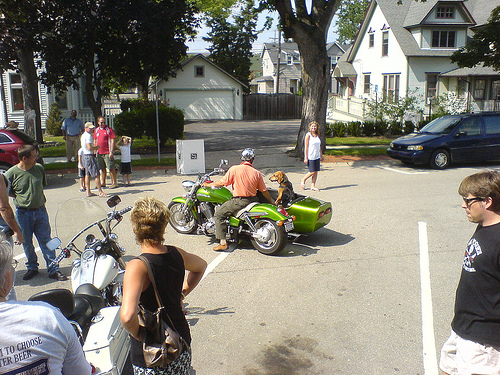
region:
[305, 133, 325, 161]
woman wearing a white tank top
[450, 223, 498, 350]
guy wearing a black tshirt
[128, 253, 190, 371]
brown purse over the woman's shoulder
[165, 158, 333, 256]
green motorcycle with side car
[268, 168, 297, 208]
dog sitting in green motorcycle side car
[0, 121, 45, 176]
red car parked on the side of the street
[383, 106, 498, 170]
van parked on the side of the street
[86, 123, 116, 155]
man wearing a red shirt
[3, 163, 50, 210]
man wearing a dark green shirt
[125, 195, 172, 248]
woman with blonde short hair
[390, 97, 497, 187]
Blue car parked in street.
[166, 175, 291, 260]
Green lime bike in lot.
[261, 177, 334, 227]
Lime green motorcycle sidecar.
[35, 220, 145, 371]
White motorcycle in lot.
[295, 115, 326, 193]
Woman in white shirt and blue shorts.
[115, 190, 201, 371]
Woman wearing black top.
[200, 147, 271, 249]
Man on lime green motorcycle.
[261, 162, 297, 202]
Dog in lime green sidecar.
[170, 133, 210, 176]
White box on street corner.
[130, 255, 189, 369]
Brown purse carried by a woman.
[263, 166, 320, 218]
dog in the sidecar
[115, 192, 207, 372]
woman with a pocketbook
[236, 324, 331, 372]
grease spot on the road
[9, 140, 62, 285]
guy with green shirt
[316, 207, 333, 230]
lights on the sidecar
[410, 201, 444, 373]
white stripe on the road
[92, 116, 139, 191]
kid next to the man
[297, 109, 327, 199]
woman with white shirt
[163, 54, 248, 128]
white garage with window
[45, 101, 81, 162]
guy standing near a bush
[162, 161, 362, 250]
Green motorcycle with sidecar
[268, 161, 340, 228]
Brown dog sitting in sidecar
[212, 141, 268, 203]
Man in silver helmet and orange shirt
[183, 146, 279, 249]
Man astride green motorcycle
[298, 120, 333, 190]
Woman in white top and blue shorts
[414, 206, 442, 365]
White parking stripe on pavement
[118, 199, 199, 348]
Blonde woman in sleeveless top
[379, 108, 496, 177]
Blue van paralleled parked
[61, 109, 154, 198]
Two adults and two children bystanders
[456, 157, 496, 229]
Blonde man with sunglasses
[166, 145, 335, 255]
man and dog in green motorcycle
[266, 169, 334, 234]
dog in motorcycle sidecar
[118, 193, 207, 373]
woman carrying brown purse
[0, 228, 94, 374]
person with gray hair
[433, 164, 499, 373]
person wearing dark gray shirt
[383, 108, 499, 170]
part of dark blue minivan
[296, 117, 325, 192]
woman wearing white shirt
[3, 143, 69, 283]
man wearing brown shoes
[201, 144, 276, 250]
man wearing orange shirt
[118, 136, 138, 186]
young boy in black shorts